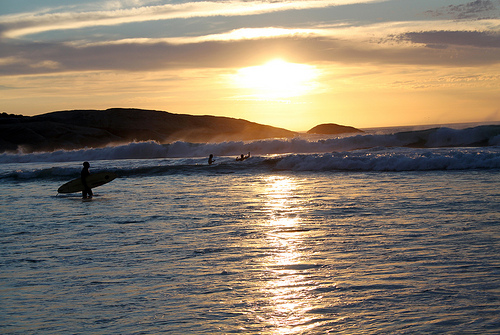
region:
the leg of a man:
[74, 176, 100, 205]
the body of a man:
[65, 132, 121, 203]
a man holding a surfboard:
[53, 150, 125, 200]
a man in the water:
[59, 151, 116, 202]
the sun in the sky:
[230, 32, 330, 113]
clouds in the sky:
[153, 20, 275, 107]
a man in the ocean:
[65, 132, 170, 229]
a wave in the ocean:
[250, 89, 434, 229]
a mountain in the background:
[50, 31, 271, 228]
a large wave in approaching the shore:
[30, 121, 499, 158]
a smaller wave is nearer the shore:
[16, 146, 498, 173]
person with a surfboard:
[58, 158, 123, 204]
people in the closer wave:
[202, 144, 260, 175]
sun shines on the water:
[228, 135, 322, 331]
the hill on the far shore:
[0, 106, 356, 139]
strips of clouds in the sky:
[1, 0, 491, 71]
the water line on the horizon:
[370, 116, 495, 133]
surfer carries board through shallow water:
[58, 142, 123, 224]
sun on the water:
[245, 188, 294, 297]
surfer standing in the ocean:
[55, 168, 125, 221]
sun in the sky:
[225, 55, 335, 95]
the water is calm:
[116, 251, 203, 293]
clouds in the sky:
[96, 30, 246, 77]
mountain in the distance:
[307, 121, 368, 138]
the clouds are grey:
[52, 48, 141, 88]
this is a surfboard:
[92, 172, 112, 189]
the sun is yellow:
[247, 73, 289, 92]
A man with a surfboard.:
[53, 153, 125, 210]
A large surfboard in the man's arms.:
[53, 169, 126, 199]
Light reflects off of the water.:
[242, 168, 323, 334]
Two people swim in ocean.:
[200, 146, 257, 175]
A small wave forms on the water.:
[13, 141, 233, 156]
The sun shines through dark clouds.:
[217, 45, 332, 103]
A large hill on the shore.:
[6, 100, 296, 144]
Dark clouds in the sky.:
[23, 15, 214, 80]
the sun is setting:
[154, 53, 428, 150]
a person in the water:
[36, 150, 120, 212]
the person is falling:
[230, 145, 257, 169]